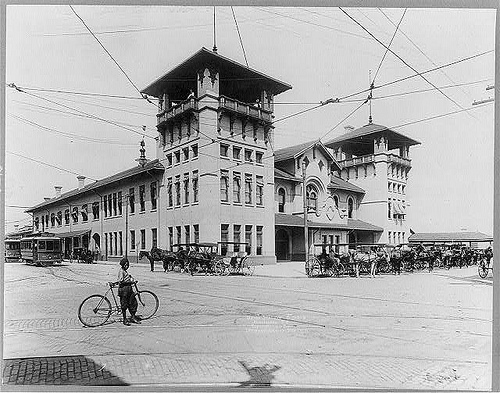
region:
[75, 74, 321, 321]
tall and old building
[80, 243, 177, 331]
person next to bike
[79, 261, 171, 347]
bike has large wheels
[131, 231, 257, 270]
two horses on carriages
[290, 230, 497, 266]
row of horses and carriages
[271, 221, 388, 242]
awning over front entrance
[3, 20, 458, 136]
wires outside building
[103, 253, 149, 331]
person near bike has dark skin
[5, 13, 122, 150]
sky is gloomy and grey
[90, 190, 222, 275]
rows of windows on building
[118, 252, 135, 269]
the head of a man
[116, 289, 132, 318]
the leg of a man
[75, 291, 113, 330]
the wheel of a bicycle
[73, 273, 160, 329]
a bicycle on the road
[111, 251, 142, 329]
a man in front of a bicycle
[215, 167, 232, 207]
a window on the building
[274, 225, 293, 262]
a door on the building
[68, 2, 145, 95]
a black wire in the air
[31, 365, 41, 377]
a brick on the ground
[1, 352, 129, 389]
a shadow on the ground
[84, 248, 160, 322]
old style bicycle with a woman standing on the side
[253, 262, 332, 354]
a street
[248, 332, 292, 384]
a street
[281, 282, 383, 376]
a street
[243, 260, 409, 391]
a street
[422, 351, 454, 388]
a street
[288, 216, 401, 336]
a street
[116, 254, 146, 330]
a man on the road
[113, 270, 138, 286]
the arm of a man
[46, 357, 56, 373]
a brick on the road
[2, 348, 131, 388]
a shadow on the road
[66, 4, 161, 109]
a black wire in the sky